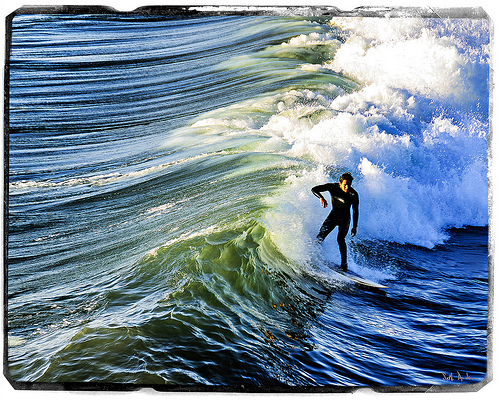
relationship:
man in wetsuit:
[309, 169, 361, 272] [316, 179, 362, 264]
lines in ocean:
[7, 13, 298, 337] [9, 10, 494, 382]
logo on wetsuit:
[337, 196, 344, 203] [311, 183, 358, 268]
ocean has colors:
[154, 100, 454, 356] [207, 193, 337, 356]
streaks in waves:
[193, 262, 479, 371] [203, 90, 348, 381]